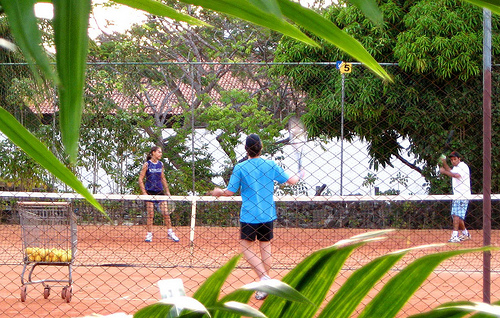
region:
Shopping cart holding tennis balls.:
[12, 191, 77, 304]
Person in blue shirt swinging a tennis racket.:
[205, 129, 309, 301]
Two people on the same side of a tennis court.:
[137, 123, 473, 245]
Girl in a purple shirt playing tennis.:
[134, 141, 183, 243]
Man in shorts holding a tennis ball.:
[435, 145, 475, 245]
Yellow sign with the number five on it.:
[335, 56, 354, 76]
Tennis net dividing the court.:
[0, 188, 498, 275]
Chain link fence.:
[0, 56, 499, 228]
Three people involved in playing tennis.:
[137, 133, 472, 297]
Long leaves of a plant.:
[95, 224, 499, 316]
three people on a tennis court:
[2, 106, 495, 301]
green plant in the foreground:
[105, 221, 485, 312]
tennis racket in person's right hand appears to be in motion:
[275, 101, 315, 191]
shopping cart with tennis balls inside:
[5, 192, 92, 303]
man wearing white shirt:
[440, 146, 470, 196]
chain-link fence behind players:
[5, 52, 485, 242]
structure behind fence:
[0, 55, 480, 226]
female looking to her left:
[130, 130, 180, 180]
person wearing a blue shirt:
[222, 117, 284, 222]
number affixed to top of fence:
[328, 55, 366, 92]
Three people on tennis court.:
[36, 32, 486, 304]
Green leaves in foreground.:
[153, 229, 450, 316]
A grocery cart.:
[11, 189, 90, 313]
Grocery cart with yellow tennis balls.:
[8, 197, 96, 307]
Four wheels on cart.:
[7, 271, 98, 310]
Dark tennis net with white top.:
[86, 186, 213, 275]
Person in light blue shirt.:
[213, 130, 310, 260]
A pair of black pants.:
[230, 202, 281, 260]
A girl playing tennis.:
[133, 141, 193, 258]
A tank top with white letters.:
[134, 153, 182, 198]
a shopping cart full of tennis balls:
[14, 197, 76, 304]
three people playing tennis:
[138, 131, 485, 296]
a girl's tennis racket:
[158, 194, 175, 215]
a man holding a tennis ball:
[431, 145, 473, 245]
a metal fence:
[6, 64, 482, 202]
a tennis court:
[66, 221, 469, 304]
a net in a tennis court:
[5, 189, 480, 275]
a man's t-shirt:
[225, 153, 289, 223]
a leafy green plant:
[121, 230, 496, 315]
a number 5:
[339, 61, 354, 73]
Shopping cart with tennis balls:
[14, 199, 106, 307]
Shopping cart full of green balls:
[10, 188, 93, 300]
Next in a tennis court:
[105, 185, 330, 298]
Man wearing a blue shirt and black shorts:
[216, 117, 286, 271]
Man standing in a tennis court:
[234, 136, 291, 266]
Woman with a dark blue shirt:
[127, 142, 203, 269]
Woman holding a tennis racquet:
[127, 140, 210, 273]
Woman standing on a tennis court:
[136, 143, 193, 249]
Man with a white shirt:
[428, 149, 496, 244]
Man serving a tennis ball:
[431, 146, 494, 252]